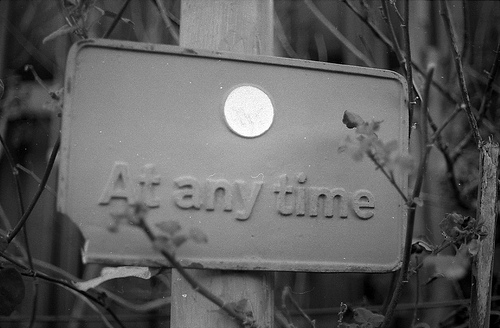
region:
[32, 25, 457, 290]
sign with raised letters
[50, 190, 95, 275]
lower corner missing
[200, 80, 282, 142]
bright circle centered on top of sign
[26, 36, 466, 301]
branches with young leaves around sign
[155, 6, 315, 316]
thick pole behind sign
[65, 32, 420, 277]
worn edges of sign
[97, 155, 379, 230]
three words on lower part of sign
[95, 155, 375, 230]
first letter of first word capitalized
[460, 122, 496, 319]
long and curved object near sign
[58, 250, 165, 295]
raw edge under sign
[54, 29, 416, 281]
a sign attached to the pole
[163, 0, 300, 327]
the pole that the sign is attached to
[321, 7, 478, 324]
some branches next to the sign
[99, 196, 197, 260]
little leaves on the branch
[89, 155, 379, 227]
the writing on the sign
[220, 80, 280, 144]
the shiny part of the sign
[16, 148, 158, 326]
some more branches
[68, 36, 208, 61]
some rusted parts of the sign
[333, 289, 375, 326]
a little flower on the branch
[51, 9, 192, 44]
some more branches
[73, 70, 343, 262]
A sign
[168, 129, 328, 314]
A sign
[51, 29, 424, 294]
The sign is grey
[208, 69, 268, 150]
There is a white circle on the sign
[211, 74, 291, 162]
The circle is in the top middle of the sign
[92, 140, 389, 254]
The sign reads At any time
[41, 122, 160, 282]
The edge of the sign is gone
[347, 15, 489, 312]
There are branches in front of the sign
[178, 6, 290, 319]
The post is tall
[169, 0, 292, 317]
The post is made of wood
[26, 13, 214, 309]
The branches are black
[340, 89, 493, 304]
The branches have small drooping leaves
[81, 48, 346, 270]
A sign is visible.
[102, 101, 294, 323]
A sign is visible.